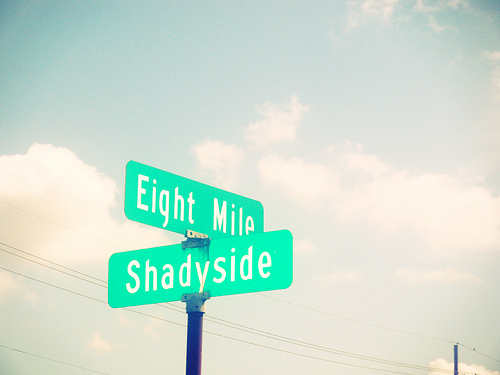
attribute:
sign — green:
[79, 171, 333, 309]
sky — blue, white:
[26, 26, 472, 331]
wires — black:
[33, 252, 427, 374]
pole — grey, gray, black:
[168, 299, 222, 365]